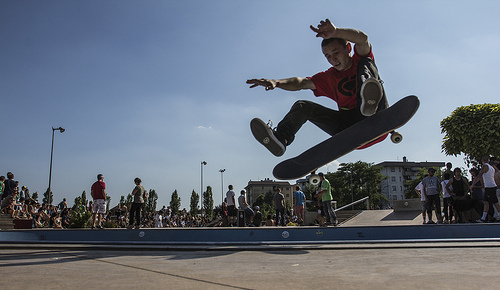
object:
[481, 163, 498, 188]
top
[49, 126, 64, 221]
streetlight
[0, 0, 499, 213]
sky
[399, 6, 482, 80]
clouds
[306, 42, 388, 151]
red tshirt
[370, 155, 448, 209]
house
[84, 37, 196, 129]
snow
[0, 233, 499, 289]
ground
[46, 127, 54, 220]
pole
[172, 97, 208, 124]
clouds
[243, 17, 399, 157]
man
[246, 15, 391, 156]
guy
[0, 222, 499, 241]
rim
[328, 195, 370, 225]
railing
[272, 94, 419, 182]
skateboard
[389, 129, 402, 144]
wheel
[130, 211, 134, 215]
knee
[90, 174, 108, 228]
man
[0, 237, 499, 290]
concrete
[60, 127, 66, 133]
light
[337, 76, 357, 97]
symbol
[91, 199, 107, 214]
shorts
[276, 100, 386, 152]
jeans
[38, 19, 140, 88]
cloud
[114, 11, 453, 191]
air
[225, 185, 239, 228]
person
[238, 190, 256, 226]
person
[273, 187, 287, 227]
person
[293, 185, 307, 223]
person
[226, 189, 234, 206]
back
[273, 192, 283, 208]
back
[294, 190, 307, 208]
back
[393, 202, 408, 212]
wall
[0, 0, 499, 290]
park